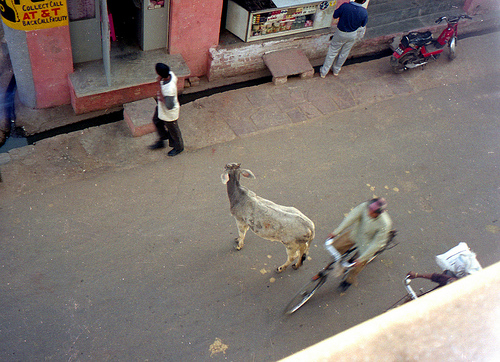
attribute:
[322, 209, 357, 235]
sleeves — long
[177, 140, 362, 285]
goat — white, gray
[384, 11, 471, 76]
scooter — red, parked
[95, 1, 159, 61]
doorway — open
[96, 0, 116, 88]
metal/gray pole — grey, metal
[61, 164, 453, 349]
road — rural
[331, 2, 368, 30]
shirt — blue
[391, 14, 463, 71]
scooter — parked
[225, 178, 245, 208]
neck — gray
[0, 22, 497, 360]
road — rural